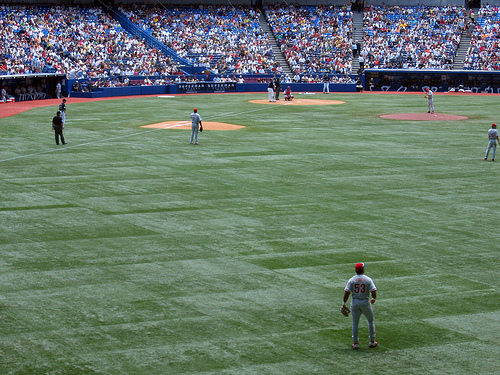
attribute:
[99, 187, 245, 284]
field — green, baseball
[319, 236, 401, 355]
player — baseball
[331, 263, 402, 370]
uniform — white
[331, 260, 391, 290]
hat — red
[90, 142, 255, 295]
field — baseball, professional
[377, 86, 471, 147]
mound — red, pitchers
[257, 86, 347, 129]
plate — home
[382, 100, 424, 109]
pants — white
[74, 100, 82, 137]
wall —   blue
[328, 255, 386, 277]
cap — red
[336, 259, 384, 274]
hat — red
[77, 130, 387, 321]
field — green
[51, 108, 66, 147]
man — black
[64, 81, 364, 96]
wall — blue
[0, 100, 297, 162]
line — white